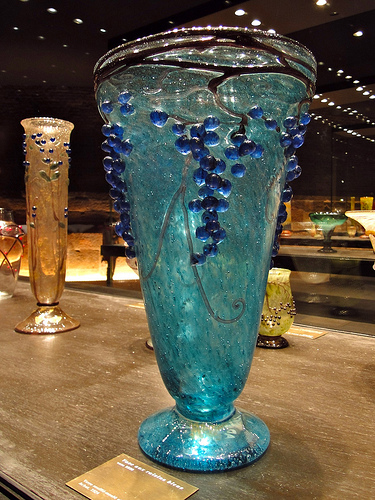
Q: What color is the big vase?
A: It is metallic blue.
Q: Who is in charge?
A: A curator.